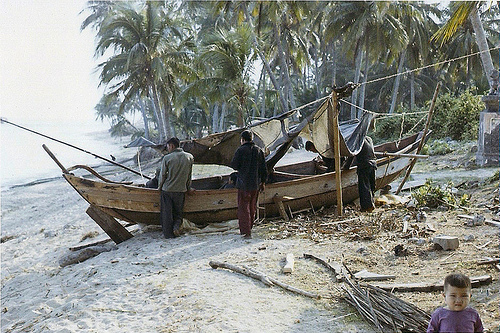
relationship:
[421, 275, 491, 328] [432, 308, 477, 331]
boy in shirt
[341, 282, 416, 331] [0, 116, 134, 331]
sticks on beach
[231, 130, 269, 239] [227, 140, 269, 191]
man in jacket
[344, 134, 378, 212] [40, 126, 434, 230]
man standing by boat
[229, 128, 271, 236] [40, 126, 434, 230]
man standing by boat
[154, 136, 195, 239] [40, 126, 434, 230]
man standing by boat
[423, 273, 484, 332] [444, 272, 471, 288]
boy with short hair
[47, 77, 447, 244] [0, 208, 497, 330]
boat on land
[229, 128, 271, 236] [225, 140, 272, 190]
man wearing shirt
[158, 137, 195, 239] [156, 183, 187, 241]
man wearing black pants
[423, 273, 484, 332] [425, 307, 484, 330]
boy wearing shirt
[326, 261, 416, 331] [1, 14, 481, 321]
sticks on beach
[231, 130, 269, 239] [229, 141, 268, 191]
man wearing a jacket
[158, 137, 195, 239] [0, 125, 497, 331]
man on a beach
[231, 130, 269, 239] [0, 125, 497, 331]
man on a beach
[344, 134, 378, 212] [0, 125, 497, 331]
man on a beach